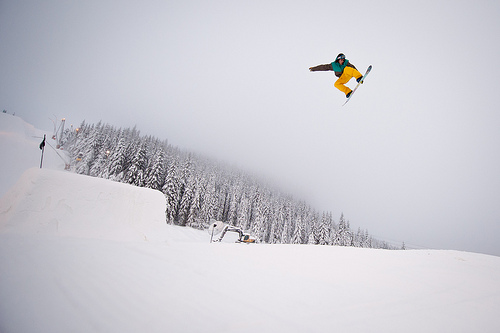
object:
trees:
[184, 185, 201, 227]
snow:
[0, 109, 499, 331]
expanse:
[0, 104, 498, 330]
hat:
[334, 48, 346, 60]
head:
[335, 52, 346, 64]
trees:
[121, 137, 150, 189]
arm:
[310, 62, 332, 72]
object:
[207, 220, 224, 244]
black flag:
[39, 133, 48, 149]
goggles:
[336, 53, 344, 59]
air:
[8, 7, 494, 322]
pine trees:
[291, 214, 304, 245]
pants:
[333, 65, 363, 95]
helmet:
[334, 53, 346, 65]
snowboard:
[341, 64, 373, 107]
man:
[308, 52, 365, 99]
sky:
[0, 0, 499, 258]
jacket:
[310, 52, 359, 78]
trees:
[289, 218, 303, 245]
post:
[40, 134, 47, 169]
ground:
[13, 112, 491, 331]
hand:
[357, 75, 368, 85]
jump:
[307, 51, 375, 108]